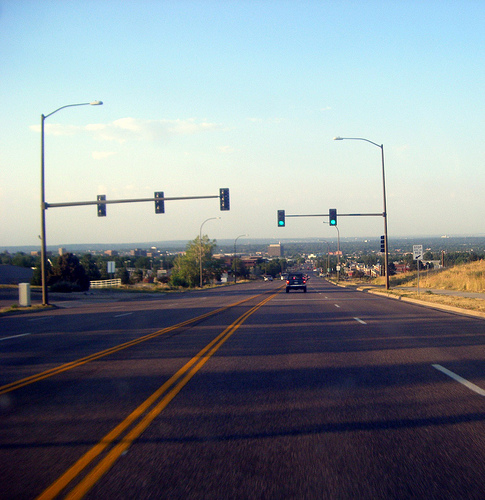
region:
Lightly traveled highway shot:
[19, 103, 470, 485]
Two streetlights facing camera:
[264, 193, 350, 233]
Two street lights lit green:
[275, 204, 339, 230]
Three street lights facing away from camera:
[87, 185, 238, 215]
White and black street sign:
[401, 233, 429, 296]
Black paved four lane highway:
[1, 291, 481, 493]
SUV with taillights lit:
[277, 265, 312, 296]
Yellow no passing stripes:
[0, 318, 234, 498]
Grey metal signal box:
[14, 274, 34, 309]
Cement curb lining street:
[350, 284, 483, 316]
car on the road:
[282, 273, 304, 291]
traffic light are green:
[279, 208, 339, 226]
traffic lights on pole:
[96, 189, 230, 217]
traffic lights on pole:
[277, 206, 342, 233]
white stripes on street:
[352, 312, 368, 332]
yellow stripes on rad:
[147, 303, 236, 388]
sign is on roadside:
[404, 239, 426, 265]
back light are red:
[285, 277, 308, 286]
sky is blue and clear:
[88, 145, 331, 192]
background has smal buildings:
[59, 241, 361, 268]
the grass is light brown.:
[436, 258, 483, 287]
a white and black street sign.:
[407, 238, 428, 298]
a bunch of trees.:
[165, 227, 221, 288]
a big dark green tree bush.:
[43, 240, 93, 298]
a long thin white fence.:
[81, 274, 126, 289]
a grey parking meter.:
[3, 275, 39, 311]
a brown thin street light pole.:
[338, 127, 396, 300]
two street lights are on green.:
[265, 199, 384, 230]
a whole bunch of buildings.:
[29, 237, 288, 284]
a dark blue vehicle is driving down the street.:
[226, 228, 355, 365]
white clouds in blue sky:
[12, 17, 45, 41]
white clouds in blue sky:
[24, 60, 105, 101]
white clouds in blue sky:
[66, 142, 113, 174]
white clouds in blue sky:
[135, 113, 184, 154]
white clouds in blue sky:
[184, 68, 262, 111]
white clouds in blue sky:
[269, 42, 369, 94]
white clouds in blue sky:
[394, 91, 432, 131]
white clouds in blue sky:
[224, 134, 256, 166]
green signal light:
[264, 202, 296, 243]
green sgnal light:
[308, 199, 346, 242]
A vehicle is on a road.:
[281, 268, 308, 295]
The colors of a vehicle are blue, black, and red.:
[281, 271, 308, 293]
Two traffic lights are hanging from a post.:
[274, 208, 389, 228]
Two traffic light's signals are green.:
[275, 208, 341, 227]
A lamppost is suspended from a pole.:
[331, 133, 385, 153]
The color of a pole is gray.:
[378, 140, 390, 289]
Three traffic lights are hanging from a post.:
[45, 185, 232, 219]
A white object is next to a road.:
[15, 280, 31, 309]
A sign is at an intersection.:
[103, 257, 117, 290]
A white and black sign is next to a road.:
[408, 240, 424, 285]